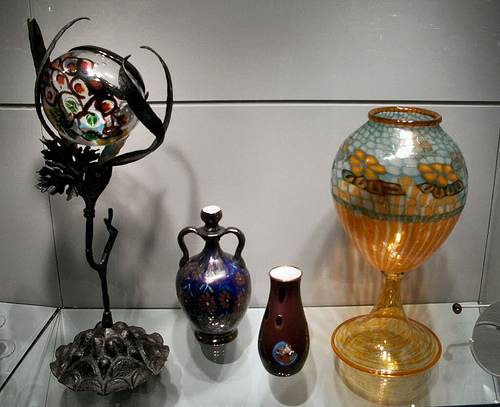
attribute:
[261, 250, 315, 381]
pottery vase — artisan , brown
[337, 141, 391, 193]
glass flower — yellow 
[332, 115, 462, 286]
glass — clear , yellow 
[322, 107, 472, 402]
item — glass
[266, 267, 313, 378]
vase — white , brown 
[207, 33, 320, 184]
wall — light grey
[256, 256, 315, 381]
vase — porcelain, Small 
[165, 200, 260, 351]
carafe — blue , Porcelain 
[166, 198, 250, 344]
carafe — oval, porcelain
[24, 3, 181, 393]
ornament — metal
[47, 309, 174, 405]
base — metal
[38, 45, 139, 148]
decoration — round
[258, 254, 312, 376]
vase — ceramic, small, maroon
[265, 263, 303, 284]
interior — white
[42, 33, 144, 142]
decoration — round, transparent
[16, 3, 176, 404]
holder — metal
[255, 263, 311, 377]
vase — small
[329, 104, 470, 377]
vase — glassy, orange, glass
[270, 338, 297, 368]
circle — small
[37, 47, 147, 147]
ball — glass, painted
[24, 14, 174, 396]
stand — metal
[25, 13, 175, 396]
art piece — glass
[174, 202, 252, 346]
art piece — glass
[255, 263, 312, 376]
art piece — glass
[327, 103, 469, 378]
art piece — glass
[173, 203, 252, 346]
vase — small, blue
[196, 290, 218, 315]
flower — red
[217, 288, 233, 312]
flower — red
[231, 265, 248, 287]
flower — red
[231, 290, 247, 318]
flower — red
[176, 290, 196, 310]
flower — red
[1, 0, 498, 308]
wall — white